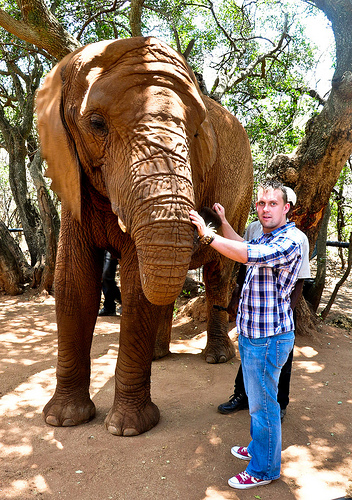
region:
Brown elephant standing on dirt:
[19, 31, 251, 437]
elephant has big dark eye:
[81, 104, 118, 145]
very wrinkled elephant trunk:
[109, 113, 213, 309]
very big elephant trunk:
[117, 127, 201, 312]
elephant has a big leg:
[35, 206, 102, 443]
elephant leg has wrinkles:
[51, 205, 93, 398]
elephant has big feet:
[34, 388, 101, 441]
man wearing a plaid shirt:
[197, 178, 325, 496]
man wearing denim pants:
[236, 324, 309, 485]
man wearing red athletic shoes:
[233, 439, 286, 498]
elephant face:
[36, 34, 213, 290]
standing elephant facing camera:
[19, 69, 245, 443]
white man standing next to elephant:
[87, 89, 349, 365]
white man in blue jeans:
[176, 152, 312, 492]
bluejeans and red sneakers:
[223, 334, 299, 493]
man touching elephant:
[17, 62, 332, 410]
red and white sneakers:
[211, 430, 284, 492]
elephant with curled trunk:
[19, 20, 253, 320]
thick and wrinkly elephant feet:
[39, 335, 174, 454]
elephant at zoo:
[7, 48, 263, 390]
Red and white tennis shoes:
[219, 435, 274, 496]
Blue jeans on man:
[232, 335, 295, 480]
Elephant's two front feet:
[30, 356, 172, 444]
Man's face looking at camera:
[244, 171, 308, 231]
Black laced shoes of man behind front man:
[210, 378, 251, 415]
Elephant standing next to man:
[24, 21, 253, 437]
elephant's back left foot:
[193, 264, 240, 384]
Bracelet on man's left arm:
[190, 214, 228, 257]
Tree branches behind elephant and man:
[229, 18, 320, 109]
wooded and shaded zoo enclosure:
[1, 0, 350, 499]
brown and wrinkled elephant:
[34, 35, 254, 436]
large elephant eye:
[86, 111, 106, 129]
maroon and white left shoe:
[227, 470, 271, 489]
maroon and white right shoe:
[229, 444, 250, 458]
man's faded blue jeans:
[237, 329, 294, 480]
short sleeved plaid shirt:
[236, 221, 302, 339]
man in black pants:
[216, 184, 310, 421]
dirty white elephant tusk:
[116, 216, 125, 233]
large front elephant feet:
[42, 398, 160, 437]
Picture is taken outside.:
[108, 14, 330, 456]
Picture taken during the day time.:
[203, 7, 346, 112]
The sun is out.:
[136, 14, 351, 81]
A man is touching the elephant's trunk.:
[200, 198, 346, 411]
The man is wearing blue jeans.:
[228, 322, 290, 460]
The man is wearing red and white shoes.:
[215, 441, 251, 493]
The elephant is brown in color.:
[19, 47, 213, 415]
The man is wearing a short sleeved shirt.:
[238, 217, 326, 359]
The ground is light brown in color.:
[14, 392, 165, 499]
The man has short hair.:
[255, 182, 287, 201]